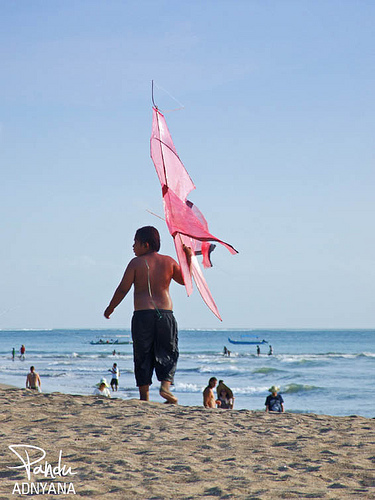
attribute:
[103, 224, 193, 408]
boy — fat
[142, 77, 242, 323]
kite — pink, light pink, dark pink, large, red, ruffly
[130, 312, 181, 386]
pants — black, long, blue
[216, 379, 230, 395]
hat — green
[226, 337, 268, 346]
boat — blue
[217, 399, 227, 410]
shirt — blue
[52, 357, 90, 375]
waves — light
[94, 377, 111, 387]
brimmed hat — white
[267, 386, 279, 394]
brimmed hat — large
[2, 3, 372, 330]
sky — grey, foggy